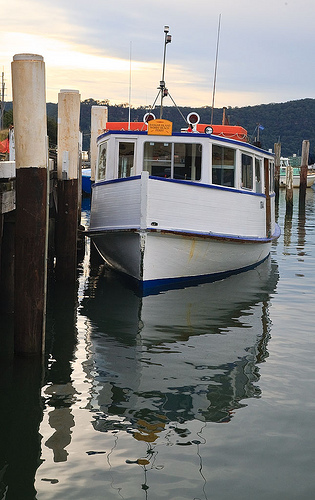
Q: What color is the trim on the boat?
A: Blue.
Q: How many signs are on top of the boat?
A: 1.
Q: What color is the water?
A: Gray.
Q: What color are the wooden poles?
A: Brown.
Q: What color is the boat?
A: White.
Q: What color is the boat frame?
A: Blue.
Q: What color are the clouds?
A: Gray.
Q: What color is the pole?
A: Gray.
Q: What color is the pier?
A: Brown.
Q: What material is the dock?
A: Wood.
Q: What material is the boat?
A: Wood.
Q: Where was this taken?
A: Harbor.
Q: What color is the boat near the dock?
A: White and blue.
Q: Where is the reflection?
A: In the water.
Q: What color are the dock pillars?
A: Brown and white.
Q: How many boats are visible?
A: 2.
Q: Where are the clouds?
A: In the sky.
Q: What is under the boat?
A: Water.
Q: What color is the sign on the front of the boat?
A: Yellow.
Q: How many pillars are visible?
A: 5.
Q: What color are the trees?
A: Green.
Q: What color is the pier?
A: Brown.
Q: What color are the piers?
A: Brown.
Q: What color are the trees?
A: Black.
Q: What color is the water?
A: Gray.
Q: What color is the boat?
A: White.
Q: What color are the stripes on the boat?
A: Blue.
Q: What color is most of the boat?
A: White.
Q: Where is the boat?
A: In the water.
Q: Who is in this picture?
A: No one.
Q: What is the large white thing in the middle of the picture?
A: Boat.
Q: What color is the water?
A: Blue.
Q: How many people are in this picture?
A: None.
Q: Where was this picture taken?
A: Docks.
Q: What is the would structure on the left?
A: Docks.